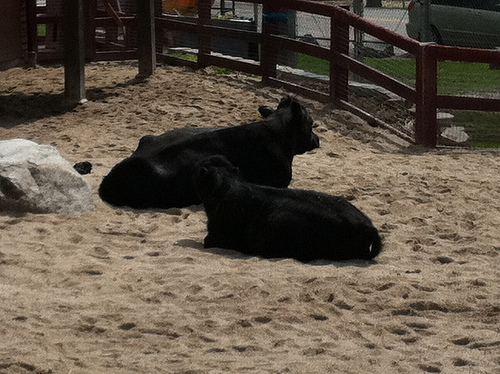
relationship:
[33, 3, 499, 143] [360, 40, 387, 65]
fence with net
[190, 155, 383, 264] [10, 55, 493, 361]
cow sits on sand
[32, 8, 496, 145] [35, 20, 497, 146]
region of grass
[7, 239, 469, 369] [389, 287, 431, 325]
sand with footprints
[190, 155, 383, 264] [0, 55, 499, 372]
cow sitting in dirt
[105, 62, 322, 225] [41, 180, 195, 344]
black cow sitting in dirt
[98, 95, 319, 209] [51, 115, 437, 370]
black cow sitting in dirt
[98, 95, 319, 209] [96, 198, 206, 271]
black cow sitting in dirt